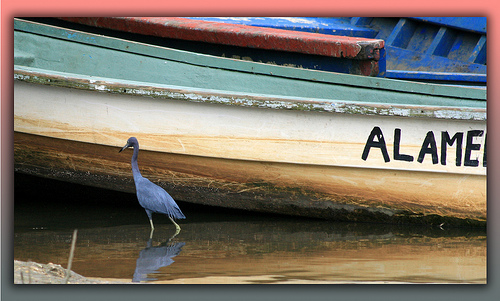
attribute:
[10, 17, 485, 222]
canoe — green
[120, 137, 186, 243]
bird — walking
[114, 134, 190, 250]
bird — gray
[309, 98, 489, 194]
name — black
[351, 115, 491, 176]
word — black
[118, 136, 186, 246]
stork — walking, grey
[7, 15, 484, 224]
boat — metal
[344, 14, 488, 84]
edge — blue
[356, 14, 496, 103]
boat — blue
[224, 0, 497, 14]
border — purple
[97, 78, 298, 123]
paint — chipped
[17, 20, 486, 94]
structure — red, blue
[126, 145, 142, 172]
neck — long